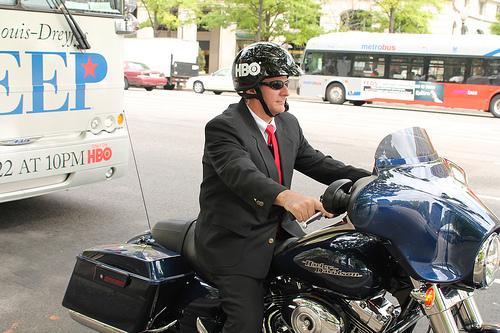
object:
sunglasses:
[259, 79, 290, 90]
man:
[194, 42, 372, 333]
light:
[105, 169, 113, 178]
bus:
[0, 0, 128, 204]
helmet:
[231, 42, 304, 92]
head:
[230, 42, 306, 114]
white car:
[186, 65, 236, 94]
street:
[0, 87, 500, 332]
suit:
[194, 103, 372, 333]